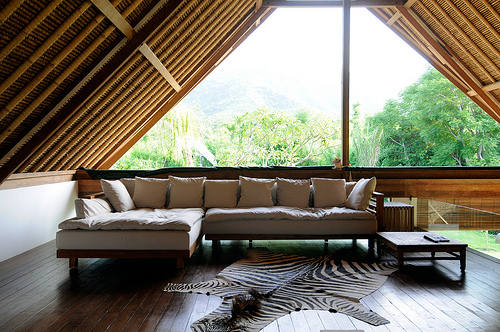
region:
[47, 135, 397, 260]
White leather sofa in middle of room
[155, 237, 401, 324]
Zebra print rug in front of sofa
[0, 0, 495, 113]
Thatched vaulted ceiling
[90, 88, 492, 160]
Lush foilage outside of window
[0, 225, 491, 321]
Brown hardwood floors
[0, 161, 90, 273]
Short white walls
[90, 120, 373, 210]
Several pillows on the sofa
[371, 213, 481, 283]
Short side table next to the sofa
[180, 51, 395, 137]
View of mountains outside of window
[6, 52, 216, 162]
Bamboo rods on under side of thatched roof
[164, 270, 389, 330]
zebra rug on a dark hardwood floor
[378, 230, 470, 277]
low dark wood coffee table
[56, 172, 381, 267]
large sectional sofa with many pillows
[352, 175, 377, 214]
tan pillow at the end of the sofa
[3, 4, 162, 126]
slanted roof of the building with open beams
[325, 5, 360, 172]
wooden beam running down the middle of the opening to the rom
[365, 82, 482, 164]
large green trees outside the window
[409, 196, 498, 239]
glass railing next to the sitting area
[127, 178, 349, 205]
six pillows along the back of the sofa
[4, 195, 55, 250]
short white wall to the side of the room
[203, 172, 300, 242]
this is a couch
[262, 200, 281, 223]
the couch is white in color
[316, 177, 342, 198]
this is a pillow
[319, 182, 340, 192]
the pillow is white in color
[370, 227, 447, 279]
this is a table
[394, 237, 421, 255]
the table is wooden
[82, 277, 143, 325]
this is the floor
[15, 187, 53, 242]
this is the wall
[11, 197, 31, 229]
the wall is white in color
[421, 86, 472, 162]
this is a tree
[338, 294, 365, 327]
part of a carpet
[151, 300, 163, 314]
part of a floor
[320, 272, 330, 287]
part of a carpet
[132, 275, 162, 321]
part of a floor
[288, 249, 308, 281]
part of a carpet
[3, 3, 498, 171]
a wooden roof over a living room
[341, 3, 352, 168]
a wooden pillar on the windowsill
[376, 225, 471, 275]
a small wooden table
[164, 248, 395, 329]
a zebra's skin on the wooden floor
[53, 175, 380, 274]
a couch in a living room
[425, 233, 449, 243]
remotes on a table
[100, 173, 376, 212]
white cushions on a couch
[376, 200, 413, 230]
a small end table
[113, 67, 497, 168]
green trees outside the window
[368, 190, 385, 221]
wooden handle of a couch